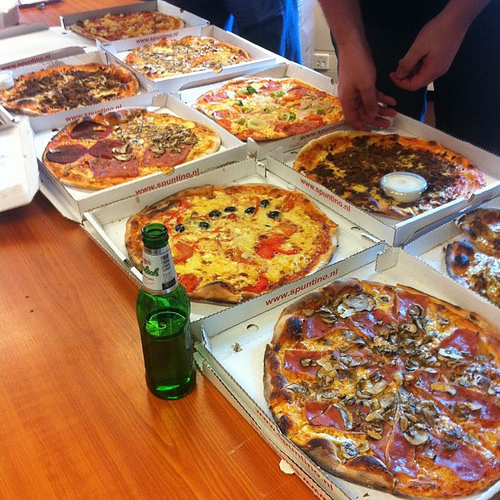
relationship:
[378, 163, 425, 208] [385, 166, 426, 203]
blue cheese in a container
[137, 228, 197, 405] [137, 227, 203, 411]
beer in a bottle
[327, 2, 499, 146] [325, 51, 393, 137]
persons right hand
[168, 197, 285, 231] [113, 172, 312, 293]
black olives on pizza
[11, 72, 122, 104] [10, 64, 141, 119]
sausage on pizza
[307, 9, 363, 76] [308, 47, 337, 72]
wall has an outlet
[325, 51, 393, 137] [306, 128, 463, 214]
right hand getting pizza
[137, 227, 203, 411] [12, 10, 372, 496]
bottle on table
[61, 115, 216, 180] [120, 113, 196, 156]
pizza has mushrooms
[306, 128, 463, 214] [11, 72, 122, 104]
pizza with sausage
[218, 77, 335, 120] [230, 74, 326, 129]
pizza with bell pepper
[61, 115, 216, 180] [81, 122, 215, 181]
pizza has ham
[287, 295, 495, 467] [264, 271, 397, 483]
pizza with burnt crust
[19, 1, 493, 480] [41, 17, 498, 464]
pizzas total nine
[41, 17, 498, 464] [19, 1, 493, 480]
nine total pizzas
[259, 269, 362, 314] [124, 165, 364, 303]
address on box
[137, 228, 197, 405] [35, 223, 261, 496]
beer on table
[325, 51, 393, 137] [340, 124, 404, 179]
hand grabbing slice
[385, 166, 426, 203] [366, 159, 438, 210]
container has sauce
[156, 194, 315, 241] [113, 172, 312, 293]
black toppings on pizza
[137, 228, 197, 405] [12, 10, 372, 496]
green bottle on table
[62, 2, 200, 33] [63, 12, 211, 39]
pizza in a box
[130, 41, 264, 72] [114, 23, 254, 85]
pizza in a box\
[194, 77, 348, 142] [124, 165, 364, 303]
pizza in a box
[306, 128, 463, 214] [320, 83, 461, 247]
pizza in a box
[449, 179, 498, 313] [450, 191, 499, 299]
pizza in a box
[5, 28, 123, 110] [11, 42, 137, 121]
pizza in a box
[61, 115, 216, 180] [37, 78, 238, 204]
pizza in a box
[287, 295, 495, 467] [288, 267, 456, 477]
pizza has mushrooms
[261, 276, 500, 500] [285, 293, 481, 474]
pizza has pepperoni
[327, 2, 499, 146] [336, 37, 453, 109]
person with hands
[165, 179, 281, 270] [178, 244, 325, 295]
pieces of tomato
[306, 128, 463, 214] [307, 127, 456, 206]
pieces of sausage